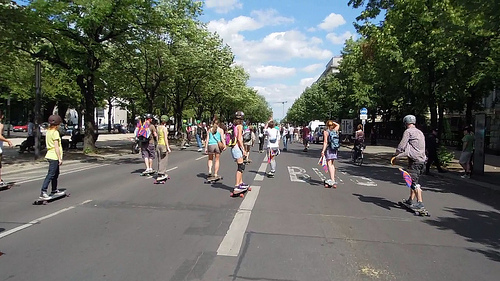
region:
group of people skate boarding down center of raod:
[38, 85, 443, 225]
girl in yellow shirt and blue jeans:
[20, 110, 78, 210]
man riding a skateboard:
[387, 106, 441, 220]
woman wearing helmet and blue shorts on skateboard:
[226, 103, 259, 200]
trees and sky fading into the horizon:
[196, 21, 353, 119]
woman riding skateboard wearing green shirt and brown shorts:
[195, 105, 227, 187]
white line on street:
[186, 204, 286, 268]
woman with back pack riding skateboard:
[316, 116, 348, 190]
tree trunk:
[63, 63, 114, 165]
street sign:
[355, 98, 377, 145]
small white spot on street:
[348, 260, 392, 274]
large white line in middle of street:
[198, 181, 270, 235]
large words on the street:
[286, 164, 408, 192]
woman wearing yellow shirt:
[29, 130, 74, 158]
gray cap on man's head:
[386, 111, 421, 128]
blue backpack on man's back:
[310, 128, 345, 156]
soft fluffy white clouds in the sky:
[243, 24, 296, 60]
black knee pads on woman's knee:
[232, 156, 268, 171]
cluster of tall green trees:
[100, 18, 242, 94]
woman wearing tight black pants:
[28, 155, 90, 186]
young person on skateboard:
[30, 111, 80, 216]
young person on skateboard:
[225, 100, 269, 218]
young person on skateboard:
[308, 120, 355, 200]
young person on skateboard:
[385, 93, 452, 243]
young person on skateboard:
[197, 107, 232, 199]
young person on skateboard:
[130, 108, 159, 185]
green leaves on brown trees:
[17, 10, 229, 110]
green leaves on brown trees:
[349, 15, 487, 108]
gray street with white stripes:
[82, 194, 384, 271]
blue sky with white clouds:
[232, 6, 332, 85]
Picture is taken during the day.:
[14, 21, 476, 256]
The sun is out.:
[28, 41, 493, 248]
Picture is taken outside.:
[16, 10, 497, 276]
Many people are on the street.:
[16, 70, 458, 262]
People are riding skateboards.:
[23, 82, 494, 251]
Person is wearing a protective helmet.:
[225, 101, 246, 131]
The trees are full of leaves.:
[23, 23, 244, 98]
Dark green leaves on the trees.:
[291, 18, 499, 85]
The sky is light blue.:
[240, 3, 357, 29]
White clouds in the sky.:
[228, 23, 300, 98]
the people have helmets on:
[68, 99, 490, 267]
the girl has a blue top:
[199, 126, 230, 148]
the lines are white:
[204, 205, 277, 262]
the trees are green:
[310, 52, 468, 109]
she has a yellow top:
[146, 121, 176, 141]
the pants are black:
[400, 158, 435, 188]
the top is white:
[256, 123, 291, 152]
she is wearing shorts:
[201, 129, 231, 184]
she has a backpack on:
[312, 128, 344, 172]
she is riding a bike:
[346, 120, 377, 164]